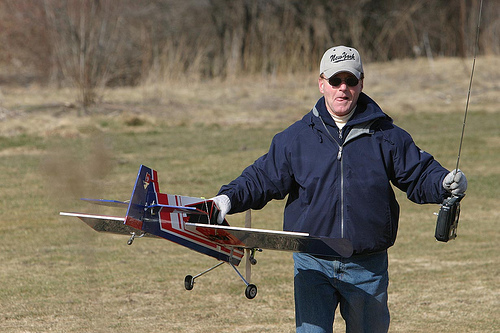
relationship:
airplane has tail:
[58, 166, 355, 298] [83, 166, 205, 231]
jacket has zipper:
[218, 91, 453, 262] [338, 145, 344, 241]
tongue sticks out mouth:
[335, 97, 344, 101] [334, 93, 348, 102]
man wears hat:
[207, 46, 468, 332] [318, 45, 364, 84]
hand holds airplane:
[207, 194, 232, 222] [58, 166, 355, 298]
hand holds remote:
[440, 168, 469, 201] [433, 1, 485, 244]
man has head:
[207, 46, 468, 332] [316, 46, 367, 119]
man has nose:
[207, 46, 468, 332] [340, 83, 347, 93]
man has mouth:
[207, 46, 468, 332] [334, 93, 348, 102]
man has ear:
[207, 46, 468, 332] [318, 79, 326, 94]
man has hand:
[207, 46, 468, 332] [207, 194, 232, 222]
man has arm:
[207, 46, 468, 332] [204, 115, 304, 224]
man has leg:
[207, 46, 468, 332] [343, 255, 392, 333]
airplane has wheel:
[58, 166, 355, 298] [244, 283, 257, 300]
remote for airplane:
[433, 1, 485, 244] [58, 166, 355, 298]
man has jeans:
[207, 46, 468, 332] [290, 247, 392, 333]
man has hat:
[207, 46, 468, 332] [318, 45, 364, 84]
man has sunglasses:
[207, 46, 468, 332] [321, 72, 363, 87]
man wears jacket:
[207, 46, 468, 332] [218, 91, 453, 262]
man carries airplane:
[207, 46, 468, 332] [58, 166, 355, 298]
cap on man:
[318, 45, 364, 84] [207, 46, 468, 332]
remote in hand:
[433, 1, 485, 244] [207, 194, 232, 222]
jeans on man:
[290, 247, 392, 333] [207, 46, 468, 332]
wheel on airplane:
[183, 273, 196, 294] [58, 166, 355, 298]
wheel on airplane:
[244, 283, 257, 300] [58, 166, 355, 298]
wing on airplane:
[189, 221, 356, 263] [58, 166, 355, 298]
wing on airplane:
[83, 166, 205, 231] [58, 166, 355, 298]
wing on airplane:
[60, 210, 158, 239] [58, 166, 355, 298]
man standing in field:
[207, 46, 468, 332] [0, 56, 497, 331]